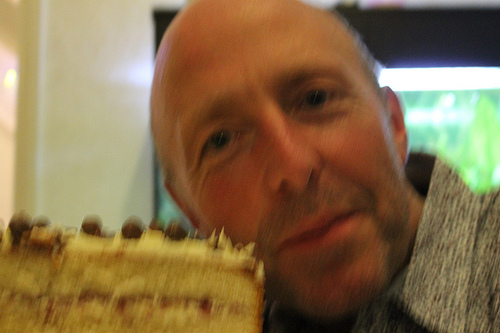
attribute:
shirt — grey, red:
[384, 147, 498, 330]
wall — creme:
[41, 2, 142, 203]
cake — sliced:
[2, 209, 269, 330]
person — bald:
[139, 4, 495, 331]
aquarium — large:
[386, 60, 498, 196]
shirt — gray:
[383, 133, 499, 312]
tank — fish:
[352, 69, 474, 131]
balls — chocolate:
[72, 199, 211, 252]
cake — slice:
[15, 196, 230, 329]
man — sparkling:
[187, 43, 388, 260]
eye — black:
[203, 110, 242, 185]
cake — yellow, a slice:
[20, 217, 264, 312]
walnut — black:
[7, 210, 39, 242]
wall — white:
[26, 9, 152, 236]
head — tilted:
[145, 9, 415, 303]